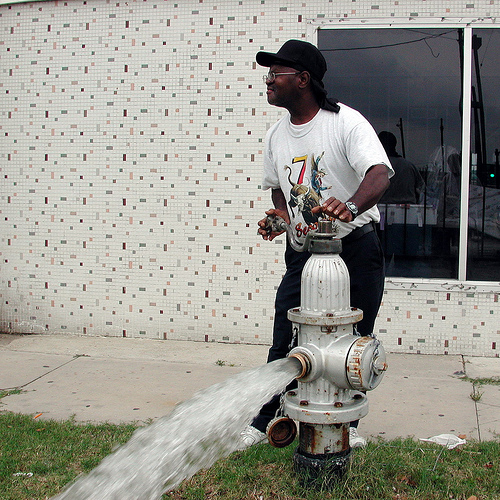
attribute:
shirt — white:
[244, 107, 399, 242]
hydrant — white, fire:
[280, 200, 380, 496]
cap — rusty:
[263, 417, 299, 450]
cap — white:
[341, 333, 387, 394]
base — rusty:
[254, 403, 368, 480]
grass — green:
[220, 461, 444, 498]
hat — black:
[252, 38, 324, 74]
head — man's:
[258, 64, 326, 107]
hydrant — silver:
[286, 218, 390, 471]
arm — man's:
[340, 167, 387, 221]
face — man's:
[263, 53, 286, 108]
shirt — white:
[250, 109, 383, 239]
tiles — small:
[57, 69, 157, 152]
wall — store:
[10, 16, 300, 339]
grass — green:
[23, 434, 467, 490]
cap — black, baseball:
[250, 39, 325, 71]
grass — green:
[372, 450, 497, 490]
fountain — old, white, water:
[260, 222, 394, 475]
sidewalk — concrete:
[10, 326, 225, 416]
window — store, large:
[323, 27, 497, 285]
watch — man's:
[344, 198, 363, 214]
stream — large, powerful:
[45, 355, 305, 498]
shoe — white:
[349, 425, 368, 449]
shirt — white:
[259, 100, 396, 252]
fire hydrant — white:
[278, 208, 385, 489]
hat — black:
[252, 36, 340, 95]